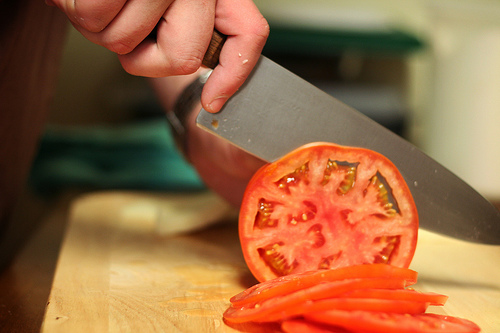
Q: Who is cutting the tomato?
A: A chef.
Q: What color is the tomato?
A: Red.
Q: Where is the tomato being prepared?
A: On a cutting board.